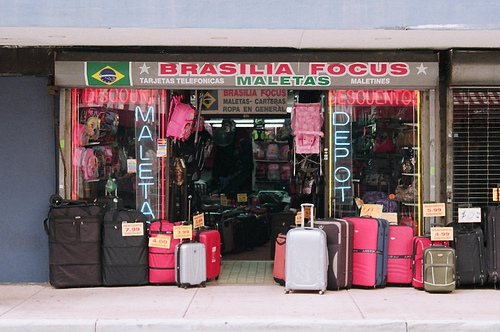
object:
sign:
[57, 60, 440, 88]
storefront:
[50, 57, 430, 288]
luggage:
[283, 225, 330, 294]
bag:
[345, 216, 389, 287]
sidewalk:
[14, 285, 477, 331]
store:
[3, 47, 485, 329]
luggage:
[102, 211, 153, 287]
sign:
[330, 101, 357, 209]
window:
[328, 87, 424, 230]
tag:
[428, 225, 455, 240]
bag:
[174, 242, 206, 286]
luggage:
[417, 243, 459, 293]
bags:
[48, 203, 148, 290]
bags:
[346, 216, 414, 286]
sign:
[81, 89, 156, 106]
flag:
[84, 62, 127, 89]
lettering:
[330, 89, 418, 107]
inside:
[171, 115, 295, 253]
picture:
[4, 9, 480, 331]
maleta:
[131, 105, 157, 212]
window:
[68, 90, 160, 203]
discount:
[79, 87, 162, 103]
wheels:
[315, 289, 321, 296]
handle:
[296, 203, 316, 233]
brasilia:
[158, 60, 298, 79]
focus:
[309, 61, 404, 80]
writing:
[156, 62, 413, 79]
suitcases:
[45, 201, 459, 292]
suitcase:
[173, 238, 206, 289]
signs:
[133, 105, 351, 208]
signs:
[84, 86, 413, 107]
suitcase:
[304, 216, 355, 292]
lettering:
[158, 63, 409, 75]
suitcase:
[446, 221, 486, 286]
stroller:
[290, 101, 322, 167]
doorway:
[167, 93, 315, 264]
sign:
[453, 207, 481, 222]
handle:
[183, 235, 195, 247]